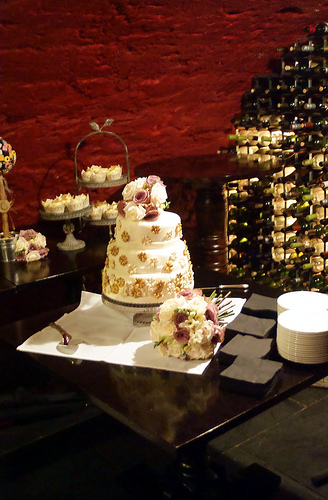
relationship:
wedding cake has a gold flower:
[97, 172, 198, 329] [138, 232, 155, 247]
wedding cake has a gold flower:
[97, 172, 198, 329] [162, 228, 174, 240]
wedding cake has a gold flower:
[97, 172, 198, 329] [115, 251, 129, 266]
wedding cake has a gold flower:
[97, 172, 198, 329] [112, 273, 126, 289]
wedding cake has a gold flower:
[97, 172, 198, 329] [114, 217, 124, 228]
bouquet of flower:
[149, 283, 252, 360] [142, 207, 162, 220]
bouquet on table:
[149, 283, 252, 360] [8, 263, 324, 381]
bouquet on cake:
[117, 175, 171, 220] [97, 208, 197, 304]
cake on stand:
[101, 174, 195, 305] [41, 208, 94, 250]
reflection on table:
[5, 262, 48, 281] [0, 222, 105, 325]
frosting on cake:
[125, 248, 133, 257] [99, 209, 194, 310]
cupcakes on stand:
[38, 191, 90, 213] [37, 205, 95, 251]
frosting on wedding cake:
[118, 255, 128, 267] [97, 171, 195, 302]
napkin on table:
[215, 360, 288, 380] [4, 259, 327, 492]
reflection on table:
[109, 358, 218, 441] [102, 365, 268, 469]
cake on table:
[106, 159, 230, 328] [1, 274, 321, 482]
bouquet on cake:
[117, 175, 171, 220] [83, 171, 196, 295]